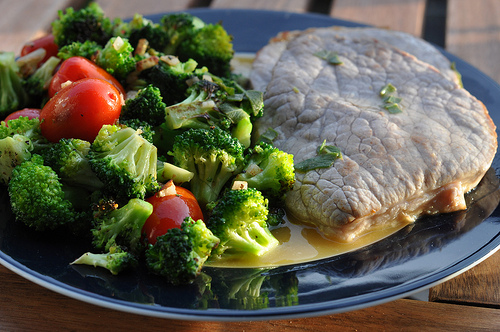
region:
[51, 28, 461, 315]
a two course meal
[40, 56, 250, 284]
tomatoes tossed with broccoli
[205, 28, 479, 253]
a piece of meat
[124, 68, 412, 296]
the food is tossed in butter sauce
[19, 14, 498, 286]
the plate is round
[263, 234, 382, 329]
the plate is blue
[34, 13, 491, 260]
the food is outside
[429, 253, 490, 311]
the table is wooden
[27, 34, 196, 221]
these are cherry tomatoes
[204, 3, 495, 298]
this is a pork chop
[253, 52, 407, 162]
the meat is halfcooked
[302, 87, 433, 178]
the meat is halfcooked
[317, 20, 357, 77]
the meat is halfcooked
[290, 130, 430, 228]
the meat is halfcooked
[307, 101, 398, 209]
the meat is halfcooked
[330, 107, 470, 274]
the meat is halfcooked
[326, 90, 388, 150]
the meat is halfcooked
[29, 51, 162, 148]
a cherry tomato on a dish.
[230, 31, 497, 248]
a piece of meat on a plate.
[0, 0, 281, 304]
a pile of green broccoli.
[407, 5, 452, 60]
a section of a chair.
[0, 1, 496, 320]
a black plate with food on it.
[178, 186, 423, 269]
a white section of a plate.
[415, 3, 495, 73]
a brown table under a plate.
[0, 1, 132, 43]
a table with a plate on it.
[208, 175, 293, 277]
a green piece of broccoli.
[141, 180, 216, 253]
a red cherry tomato.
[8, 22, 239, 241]
a pile of vegetables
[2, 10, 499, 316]
the round blue plate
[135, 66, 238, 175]
the cooked broccoli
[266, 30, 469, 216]
the cooked piece of meat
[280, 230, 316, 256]
the yellow part of the plate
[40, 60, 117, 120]
the cooked red tomatoes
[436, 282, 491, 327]
a part of the wooden table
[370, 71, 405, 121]
the green vegetables on the meat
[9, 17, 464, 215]
cooked food on the plate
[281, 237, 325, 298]
where the yellow and blue meet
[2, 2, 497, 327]
a blue dish with food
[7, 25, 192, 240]
grape tomatoes in middle of broccoli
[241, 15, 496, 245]
a piece of meat on blue dish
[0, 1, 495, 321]
dish is ceramic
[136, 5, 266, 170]
pieces of cooked broccoli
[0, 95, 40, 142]
a grape tomato under broccoli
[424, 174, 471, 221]
a piece of bone in meat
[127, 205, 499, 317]
dish is white in the center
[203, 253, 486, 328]
border of dish is blue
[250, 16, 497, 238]
meat is not well cooked